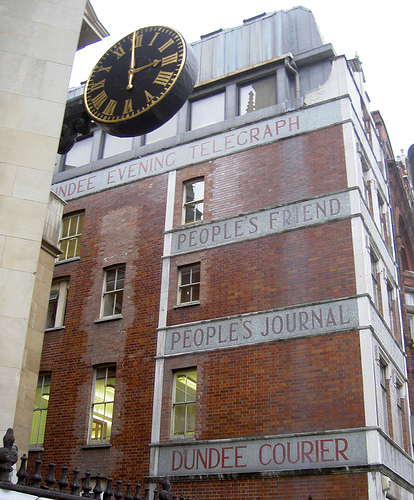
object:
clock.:
[87, 26, 193, 129]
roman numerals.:
[159, 48, 181, 67]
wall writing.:
[163, 194, 356, 250]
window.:
[176, 168, 210, 230]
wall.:
[48, 139, 393, 493]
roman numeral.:
[156, 36, 176, 55]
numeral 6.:
[121, 95, 135, 116]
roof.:
[189, 0, 312, 42]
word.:
[268, 194, 348, 237]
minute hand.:
[125, 34, 141, 80]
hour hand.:
[133, 57, 160, 77]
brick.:
[262, 156, 278, 183]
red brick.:
[249, 156, 263, 180]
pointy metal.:
[132, 56, 163, 74]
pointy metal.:
[18, 458, 155, 500]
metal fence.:
[7, 453, 170, 498]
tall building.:
[49, 65, 413, 497]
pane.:
[233, 80, 278, 113]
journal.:
[258, 307, 353, 339]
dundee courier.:
[164, 438, 353, 473]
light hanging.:
[61, 111, 97, 150]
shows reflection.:
[182, 181, 203, 223]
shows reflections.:
[236, 85, 259, 114]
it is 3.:
[118, 25, 171, 91]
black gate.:
[3, 423, 187, 499]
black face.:
[88, 29, 184, 123]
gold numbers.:
[91, 90, 109, 108]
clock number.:
[149, 27, 157, 47]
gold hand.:
[126, 33, 138, 85]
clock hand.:
[135, 55, 175, 75]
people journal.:
[170, 302, 355, 351]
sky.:
[343, 1, 414, 110]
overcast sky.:
[342, 0, 413, 72]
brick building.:
[68, 83, 411, 500]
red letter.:
[326, 197, 345, 220]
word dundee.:
[157, 443, 259, 479]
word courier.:
[256, 432, 360, 473]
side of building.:
[368, 124, 409, 423]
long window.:
[371, 251, 381, 312]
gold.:
[181, 38, 189, 65]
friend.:
[260, 197, 345, 230]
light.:
[245, 85, 259, 112]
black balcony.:
[397, 211, 411, 272]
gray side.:
[346, 63, 373, 117]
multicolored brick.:
[270, 147, 332, 198]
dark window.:
[188, 89, 226, 129]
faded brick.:
[213, 162, 247, 213]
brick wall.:
[67, 178, 404, 496]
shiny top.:
[235, 61, 282, 122]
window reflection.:
[233, 82, 283, 120]